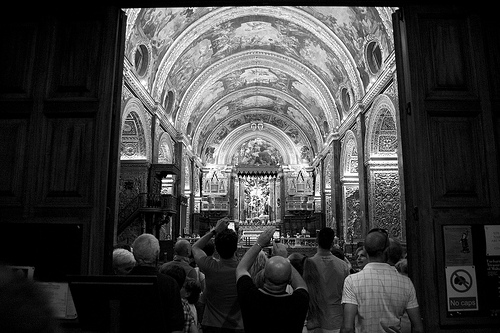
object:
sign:
[443, 261, 483, 312]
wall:
[392, 6, 484, 330]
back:
[242, 295, 308, 325]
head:
[129, 232, 162, 265]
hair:
[130, 231, 165, 262]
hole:
[127, 41, 156, 77]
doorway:
[60, 3, 427, 332]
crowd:
[120, 222, 420, 322]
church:
[0, 3, 500, 333]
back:
[234, 174, 280, 226]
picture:
[274, 232, 277, 240]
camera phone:
[272, 227, 281, 243]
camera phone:
[228, 219, 238, 232]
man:
[189, 214, 260, 329]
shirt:
[342, 260, 416, 331]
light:
[160, 173, 176, 195]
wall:
[116, 134, 200, 234]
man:
[231, 223, 312, 333]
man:
[152, 238, 208, 331]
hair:
[129, 232, 162, 272]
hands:
[256, 226, 281, 249]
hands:
[216, 217, 230, 230]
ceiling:
[115, 13, 400, 164]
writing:
[448, 293, 478, 313]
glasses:
[368, 230, 389, 236]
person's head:
[363, 229, 390, 262]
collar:
[363, 261, 393, 274]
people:
[157, 240, 198, 310]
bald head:
[265, 256, 292, 288]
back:
[214, 228, 238, 308]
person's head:
[211, 226, 239, 260]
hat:
[434, 261, 497, 331]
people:
[296, 225, 351, 332]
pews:
[267, 241, 317, 256]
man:
[330, 223, 420, 332]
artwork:
[118, 6, 399, 172]